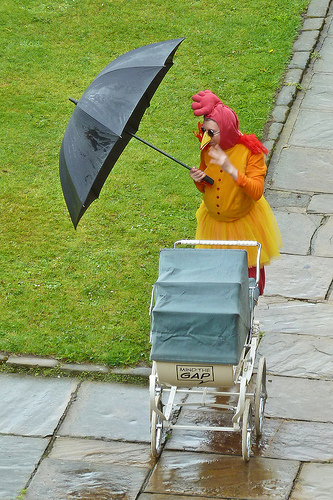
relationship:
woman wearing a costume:
[185, 91, 278, 299] [189, 87, 271, 276]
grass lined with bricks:
[21, 271, 104, 350] [30, 360, 125, 400]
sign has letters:
[173, 364, 220, 381] [175, 362, 210, 382]